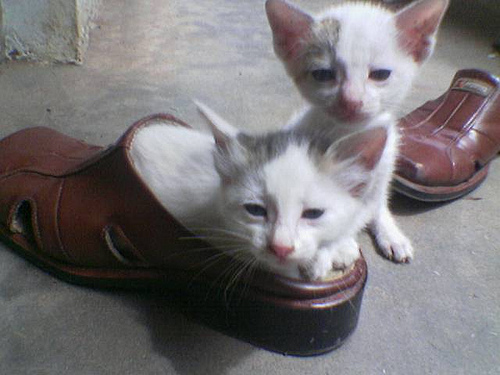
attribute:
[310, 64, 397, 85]
eyes — dark, blue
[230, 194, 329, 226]
eyes — dark, blue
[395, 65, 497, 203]
shoe — brown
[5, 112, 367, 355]
shoe — brown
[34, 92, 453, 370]
clogs — brown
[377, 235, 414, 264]
paw — white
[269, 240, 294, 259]
nose — pink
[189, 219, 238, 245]
kitten whisker — white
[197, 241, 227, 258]
kitten whisker — white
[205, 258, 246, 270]
kitten whisker — white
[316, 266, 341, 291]
kitten whisker — white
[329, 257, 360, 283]
kitten whisker — white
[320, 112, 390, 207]
ear — pink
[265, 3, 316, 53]
ear — pink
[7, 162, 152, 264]
shoe — brown, shiny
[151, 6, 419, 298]
kittens — small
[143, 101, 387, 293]
cat — white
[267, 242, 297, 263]
kitten nose — small, pink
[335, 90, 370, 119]
kitten's noses — pink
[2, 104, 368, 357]
brown shoe — brown 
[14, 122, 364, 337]
sandal — brown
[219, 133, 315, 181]
fur — grey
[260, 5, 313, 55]
ear — large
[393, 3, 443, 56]
ear — large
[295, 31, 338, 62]
fur — dark